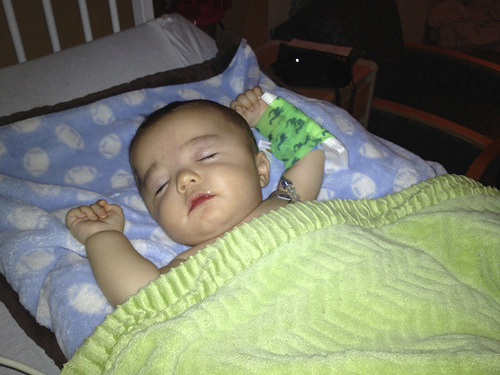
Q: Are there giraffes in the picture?
A: No, there are no giraffes.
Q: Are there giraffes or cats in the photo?
A: No, there are no giraffes or cats.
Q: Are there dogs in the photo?
A: No, there are no dogs.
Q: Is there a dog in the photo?
A: No, there are no dogs.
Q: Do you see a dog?
A: No, there are no dogs.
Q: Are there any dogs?
A: No, there are no dogs.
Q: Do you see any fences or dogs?
A: No, there are no dogs or fences.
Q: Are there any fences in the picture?
A: No, there are no fences.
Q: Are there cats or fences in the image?
A: No, there are no fences or cats.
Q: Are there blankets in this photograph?
A: Yes, there is a blanket.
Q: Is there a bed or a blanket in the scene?
A: Yes, there is a blanket.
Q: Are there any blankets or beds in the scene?
A: Yes, there is a blanket.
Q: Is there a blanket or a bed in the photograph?
A: Yes, there is a blanket.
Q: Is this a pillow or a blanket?
A: This is a blanket.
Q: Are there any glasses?
A: No, there are no glasses.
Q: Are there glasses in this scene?
A: No, there are no glasses.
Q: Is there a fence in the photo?
A: No, there are no fences.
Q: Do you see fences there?
A: No, there are no fences.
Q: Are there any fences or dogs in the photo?
A: No, there are no fences or dogs.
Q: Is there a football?
A: Yes, there is a football.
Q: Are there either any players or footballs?
A: Yes, there is a football.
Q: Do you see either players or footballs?
A: Yes, there is a football.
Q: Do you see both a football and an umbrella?
A: No, there is a football but no umbrellas.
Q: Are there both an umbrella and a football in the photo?
A: No, there is a football but no umbrellas.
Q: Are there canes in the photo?
A: No, there are no canes.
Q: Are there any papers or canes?
A: No, there are no canes or papers.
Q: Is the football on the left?
A: Yes, the football is on the left of the image.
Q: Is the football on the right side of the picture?
A: No, the football is on the left of the image.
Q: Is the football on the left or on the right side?
A: The football is on the left of the image.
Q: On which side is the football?
A: The football is on the left of the image.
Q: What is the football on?
A: The football is on the blanket.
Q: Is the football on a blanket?
A: Yes, the football is on a blanket.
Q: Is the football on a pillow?
A: No, the football is on a blanket.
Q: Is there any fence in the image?
A: No, there are no fences.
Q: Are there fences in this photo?
A: No, there are no fences.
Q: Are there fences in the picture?
A: No, there are no fences.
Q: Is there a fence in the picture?
A: No, there are no fences.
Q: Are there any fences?
A: No, there are no fences.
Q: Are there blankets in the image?
A: Yes, there is a blanket.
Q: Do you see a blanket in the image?
A: Yes, there is a blanket.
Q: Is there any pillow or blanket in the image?
A: Yes, there is a blanket.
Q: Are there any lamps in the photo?
A: No, there are no lamps.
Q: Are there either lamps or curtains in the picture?
A: No, there are no lamps or curtains.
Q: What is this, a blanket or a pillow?
A: This is a blanket.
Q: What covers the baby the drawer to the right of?
A: The blanket covers the baby.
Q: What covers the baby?
A: The blanket covers the baby.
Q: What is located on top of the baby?
A: The blanket is on top of the baby.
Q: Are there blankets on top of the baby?
A: Yes, there is a blanket on top of the baby.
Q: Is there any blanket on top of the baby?
A: Yes, there is a blanket on top of the baby.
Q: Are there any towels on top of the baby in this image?
A: No, there is a blanket on top of the baby.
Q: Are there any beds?
A: Yes, there is a bed.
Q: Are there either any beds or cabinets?
A: Yes, there is a bed.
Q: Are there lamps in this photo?
A: No, there are no lamps.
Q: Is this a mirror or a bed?
A: This is a bed.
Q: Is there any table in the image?
A: Yes, there is a table.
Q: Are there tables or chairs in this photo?
A: Yes, there is a table.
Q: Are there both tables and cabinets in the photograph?
A: No, there is a table but no cabinets.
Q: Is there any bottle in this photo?
A: No, there are no bottles.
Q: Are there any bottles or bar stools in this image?
A: No, there are no bottles or bar stools.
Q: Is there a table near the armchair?
A: Yes, there is a table near the armchair.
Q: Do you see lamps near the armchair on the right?
A: No, there is a table near the armchair.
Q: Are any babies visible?
A: Yes, there is a baby.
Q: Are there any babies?
A: Yes, there is a baby.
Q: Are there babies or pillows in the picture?
A: Yes, there is a baby.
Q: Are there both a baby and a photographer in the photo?
A: No, there is a baby but no photographers.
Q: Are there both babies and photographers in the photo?
A: No, there is a baby but no photographers.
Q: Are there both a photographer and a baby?
A: No, there is a baby but no photographers.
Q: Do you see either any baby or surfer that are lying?
A: Yes, the baby is lying.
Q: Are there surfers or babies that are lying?
A: Yes, the baby is lying.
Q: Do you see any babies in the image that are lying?
A: Yes, there is a baby that is lying.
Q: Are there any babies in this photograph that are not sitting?
A: Yes, there is a baby that is lying.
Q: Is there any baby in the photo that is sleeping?
A: Yes, there is a baby that is sleeping.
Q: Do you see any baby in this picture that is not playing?
A: Yes, there is a baby that is sleeping .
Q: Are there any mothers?
A: No, there are no mothers.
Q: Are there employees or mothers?
A: No, there are no mothers or employees.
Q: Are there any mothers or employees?
A: No, there are no mothers or employees.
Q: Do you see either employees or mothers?
A: No, there are no mothers or employees.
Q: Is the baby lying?
A: Yes, the baby is lying.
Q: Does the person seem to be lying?
A: Yes, the baby is lying.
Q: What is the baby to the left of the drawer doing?
A: The baby is lying.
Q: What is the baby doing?
A: The baby is lying.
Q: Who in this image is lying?
A: The baby is lying.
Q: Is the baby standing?
A: No, the baby is lying.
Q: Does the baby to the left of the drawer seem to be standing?
A: No, the baby is lying.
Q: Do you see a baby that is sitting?
A: No, there is a baby but he is lying.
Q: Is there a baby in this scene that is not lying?
A: No, there is a baby but he is lying.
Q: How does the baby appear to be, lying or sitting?
A: The baby is lying.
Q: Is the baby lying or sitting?
A: The baby is lying.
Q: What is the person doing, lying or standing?
A: The baby is lying.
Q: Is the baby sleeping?
A: Yes, the baby is sleeping.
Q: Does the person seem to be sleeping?
A: Yes, the baby is sleeping.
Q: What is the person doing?
A: The baby is sleeping.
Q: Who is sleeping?
A: The baby is sleeping.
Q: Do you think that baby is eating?
A: No, the baby is sleeping.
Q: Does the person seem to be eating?
A: No, the baby is sleeping.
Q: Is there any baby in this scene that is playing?
A: No, there is a baby but he is sleeping.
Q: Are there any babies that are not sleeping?
A: No, there is a baby but he is sleeping.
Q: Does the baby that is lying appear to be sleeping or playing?
A: The baby is sleeping.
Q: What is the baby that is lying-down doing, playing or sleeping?
A: The baby is sleeping.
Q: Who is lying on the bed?
A: The baby is lying on the bed.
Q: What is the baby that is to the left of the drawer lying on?
A: The baby is lying on the bed.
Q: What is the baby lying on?
A: The baby is lying on the bed.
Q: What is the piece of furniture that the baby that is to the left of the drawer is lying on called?
A: The piece of furniture is a bed.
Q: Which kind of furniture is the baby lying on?
A: The baby is lying on the bed.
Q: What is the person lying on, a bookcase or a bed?
A: The baby is lying on a bed.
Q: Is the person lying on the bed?
A: Yes, the baby is lying on the bed.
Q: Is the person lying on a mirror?
A: No, the baby is lying on the bed.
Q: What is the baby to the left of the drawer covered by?
A: The baby is covered by the blanket.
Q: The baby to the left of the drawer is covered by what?
A: The baby is covered by the blanket.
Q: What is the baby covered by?
A: The baby is covered by the blanket.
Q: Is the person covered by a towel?
A: No, the baby is covered by the blanket.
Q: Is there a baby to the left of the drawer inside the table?
A: Yes, there is a baby to the left of the drawer.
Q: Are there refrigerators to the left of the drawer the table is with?
A: No, there is a baby to the left of the drawer.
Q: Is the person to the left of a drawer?
A: Yes, the baby is to the left of a drawer.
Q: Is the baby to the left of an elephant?
A: No, the baby is to the left of a drawer.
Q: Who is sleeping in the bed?
A: The baby is sleeping in the bed.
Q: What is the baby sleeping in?
A: The baby is sleeping in the bed.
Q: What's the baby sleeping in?
A: The baby is sleeping in the bed.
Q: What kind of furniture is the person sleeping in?
A: The baby is sleeping in the bed.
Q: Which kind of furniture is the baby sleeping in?
A: The baby is sleeping in the bed.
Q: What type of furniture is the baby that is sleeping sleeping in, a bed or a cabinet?
A: The baby is sleeping in a bed.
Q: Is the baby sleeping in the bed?
A: Yes, the baby is sleeping in the bed.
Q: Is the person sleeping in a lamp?
A: No, the baby is sleeping in the bed.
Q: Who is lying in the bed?
A: The baby is lying in the bed.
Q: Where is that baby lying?
A: The baby is lying in the bed.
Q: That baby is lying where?
A: The baby is lying in the bed.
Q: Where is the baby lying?
A: The baby is lying in the bed.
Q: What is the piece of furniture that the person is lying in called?
A: The piece of furniture is a bed.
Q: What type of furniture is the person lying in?
A: The baby is lying in the bed.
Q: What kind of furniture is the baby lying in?
A: The baby is lying in the bed.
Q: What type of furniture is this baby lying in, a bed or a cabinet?
A: The baby is lying in a bed.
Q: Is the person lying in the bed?
A: Yes, the baby is lying in the bed.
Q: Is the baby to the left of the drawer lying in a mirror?
A: No, the baby is lying in the bed.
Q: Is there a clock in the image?
A: No, there are no clocks.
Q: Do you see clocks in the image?
A: No, there are no clocks.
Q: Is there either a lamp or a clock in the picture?
A: No, there are no clocks or lamps.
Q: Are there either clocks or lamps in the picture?
A: No, there are no clocks or lamps.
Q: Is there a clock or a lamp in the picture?
A: No, there are no clocks or lamps.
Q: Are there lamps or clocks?
A: No, there are no clocks or lamps.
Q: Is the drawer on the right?
A: Yes, the drawer is on the right of the image.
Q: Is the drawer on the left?
A: No, the drawer is on the right of the image.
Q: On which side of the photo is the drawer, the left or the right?
A: The drawer is on the right of the image.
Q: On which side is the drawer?
A: The drawer is on the right of the image.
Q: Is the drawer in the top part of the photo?
A: Yes, the drawer is in the top of the image.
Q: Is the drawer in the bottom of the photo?
A: No, the drawer is in the top of the image.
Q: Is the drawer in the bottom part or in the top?
A: The drawer is in the top of the image.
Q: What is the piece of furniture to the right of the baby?
A: The piece of furniture is a drawer.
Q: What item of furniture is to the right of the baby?
A: The piece of furniture is a drawer.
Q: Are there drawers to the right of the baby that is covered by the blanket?
A: Yes, there is a drawer to the right of the baby.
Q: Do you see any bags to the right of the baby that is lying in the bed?
A: No, there is a drawer to the right of the baby.